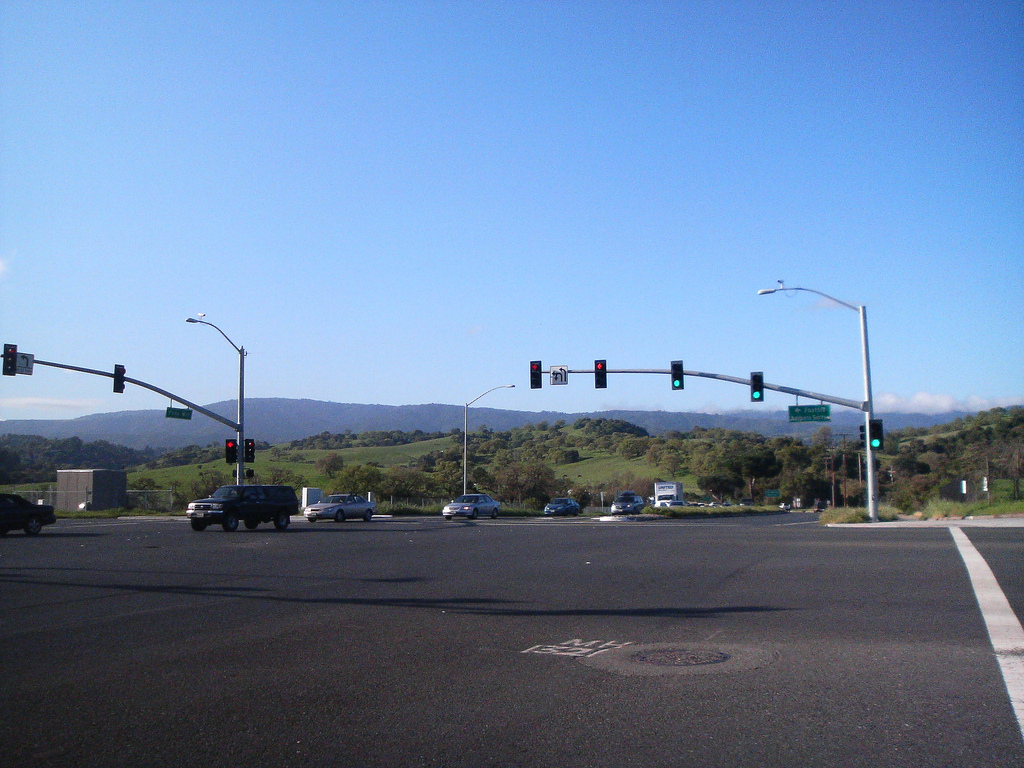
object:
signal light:
[673, 360, 686, 390]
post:
[859, 305, 876, 522]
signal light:
[750, 371, 764, 402]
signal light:
[859, 418, 883, 451]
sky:
[0, 0, 1024, 424]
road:
[0, 514, 1024, 768]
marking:
[520, 637, 633, 658]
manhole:
[580, 640, 782, 679]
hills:
[0, 417, 904, 522]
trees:
[487, 444, 556, 510]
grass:
[551, 451, 704, 498]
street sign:
[788, 404, 831, 423]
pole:
[756, 279, 879, 524]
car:
[186, 484, 301, 532]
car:
[441, 493, 501, 523]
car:
[0, 494, 58, 538]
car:
[544, 497, 580, 516]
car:
[611, 492, 646, 517]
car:
[778, 502, 791, 511]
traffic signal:
[225, 438, 236, 464]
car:
[302, 494, 376, 524]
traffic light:
[2, 343, 35, 377]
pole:
[28, 360, 241, 432]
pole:
[539, 367, 868, 410]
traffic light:
[594, 360, 607, 390]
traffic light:
[529, 360, 542, 390]